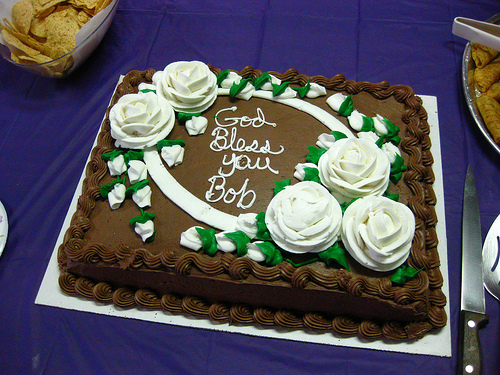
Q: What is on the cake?
A: There are letters on the cake.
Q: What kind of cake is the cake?
A: Chocolate.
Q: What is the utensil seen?
A: Knife.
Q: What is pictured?
A: Cake.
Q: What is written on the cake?
A: God Bless you Bob.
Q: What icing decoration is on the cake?
A: Flowers.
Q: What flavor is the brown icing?
A: Chocolate.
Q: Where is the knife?
A: By the cake.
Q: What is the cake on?
A: A table.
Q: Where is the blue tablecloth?
A: Under the cake.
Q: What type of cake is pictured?
A: Sheet cake.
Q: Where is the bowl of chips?
A: In the top left.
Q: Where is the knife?
A: Right side of cake.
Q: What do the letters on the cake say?
A: God bless you Bob.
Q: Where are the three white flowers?
A: Right side of cake.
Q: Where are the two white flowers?
A: Upper left side of cake.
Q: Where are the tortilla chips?
A: Upper left of cake.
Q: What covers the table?
A: Blue tablecloth.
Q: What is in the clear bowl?
A: Tortilla chips.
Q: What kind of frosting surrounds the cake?
A: Chocolate frosting.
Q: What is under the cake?
A: Cardboard.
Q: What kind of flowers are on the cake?
A: White roses.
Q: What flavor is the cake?
A: Chocolate.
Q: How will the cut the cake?
A: Knife.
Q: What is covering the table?
A: Tablecloth.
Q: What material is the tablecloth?
A: Plastic.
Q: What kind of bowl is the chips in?
A: Glass.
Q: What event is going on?
A: Party.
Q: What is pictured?
A: Cake.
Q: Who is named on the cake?
A: Bob.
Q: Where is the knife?
A: Table.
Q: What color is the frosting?
A: Brown.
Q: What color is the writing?
A: White.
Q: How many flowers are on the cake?
A: 5.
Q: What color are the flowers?
A: White.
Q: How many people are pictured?
A: 0.